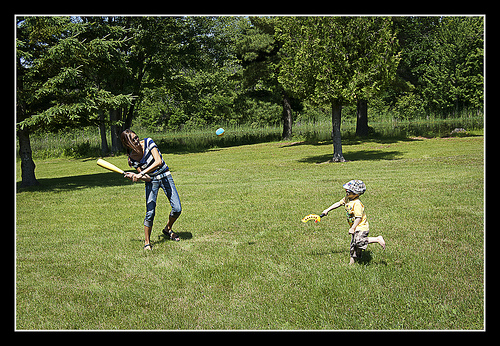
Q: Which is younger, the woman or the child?
A: The child is younger than the woman.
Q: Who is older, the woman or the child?
A: The woman is older than the child.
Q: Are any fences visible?
A: No, there are no fences.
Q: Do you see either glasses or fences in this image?
A: No, there are no fences or glasses.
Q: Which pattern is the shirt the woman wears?
A: The shirt is striped.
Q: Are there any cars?
A: No, there are no cars.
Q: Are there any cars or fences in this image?
A: No, there are no cars or fences.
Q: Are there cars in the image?
A: No, there are no cars.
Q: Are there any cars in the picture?
A: No, there are no cars.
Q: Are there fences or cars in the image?
A: No, there are no cars or fences.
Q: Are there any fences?
A: No, there are no fences.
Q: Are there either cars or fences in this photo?
A: No, there are no fences or cars.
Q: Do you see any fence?
A: No, there are no fences.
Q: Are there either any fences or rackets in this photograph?
A: No, there are no fences or rackets.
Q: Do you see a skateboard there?
A: No, there are no skateboards.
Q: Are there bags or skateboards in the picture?
A: No, there are no skateboards or bags.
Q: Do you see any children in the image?
A: Yes, there is a child.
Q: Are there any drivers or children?
A: Yes, there is a child.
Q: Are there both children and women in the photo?
A: Yes, there are both a child and a woman.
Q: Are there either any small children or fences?
A: Yes, there is a small child.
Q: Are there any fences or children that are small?
A: Yes, the child is small.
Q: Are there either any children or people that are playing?
A: Yes, the child is playing.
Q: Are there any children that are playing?
A: Yes, there is a child that is playing.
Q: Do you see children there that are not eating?
A: Yes, there is a child that is playing .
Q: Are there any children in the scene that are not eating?
A: Yes, there is a child that is playing.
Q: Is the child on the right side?
A: Yes, the child is on the right of the image.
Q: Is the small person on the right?
A: Yes, the child is on the right of the image.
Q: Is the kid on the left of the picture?
A: No, the kid is on the right of the image.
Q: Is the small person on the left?
A: No, the kid is on the right of the image.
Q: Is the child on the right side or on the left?
A: The child is on the right of the image.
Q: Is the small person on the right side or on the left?
A: The child is on the right of the image.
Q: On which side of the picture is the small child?
A: The child is on the right of the image.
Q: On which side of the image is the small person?
A: The child is on the right of the image.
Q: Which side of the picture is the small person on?
A: The child is on the right of the image.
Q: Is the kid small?
A: Yes, the kid is small.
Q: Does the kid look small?
A: Yes, the kid is small.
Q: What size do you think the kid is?
A: The kid is small.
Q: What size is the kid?
A: The kid is small.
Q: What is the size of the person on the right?
A: The kid is small.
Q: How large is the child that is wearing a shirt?
A: The child is small.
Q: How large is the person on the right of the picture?
A: The child is small.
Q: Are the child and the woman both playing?
A: Yes, both the child and the woman are playing.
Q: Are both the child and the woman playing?
A: Yes, both the child and the woman are playing.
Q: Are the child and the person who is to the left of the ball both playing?
A: Yes, both the child and the woman are playing.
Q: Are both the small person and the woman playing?
A: Yes, both the child and the woman are playing.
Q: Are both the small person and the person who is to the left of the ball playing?
A: Yes, both the child and the woman are playing.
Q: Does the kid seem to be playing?
A: Yes, the kid is playing.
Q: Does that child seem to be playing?
A: Yes, the child is playing.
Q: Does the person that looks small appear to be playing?
A: Yes, the child is playing.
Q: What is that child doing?
A: The child is playing.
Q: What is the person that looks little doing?
A: The child is playing.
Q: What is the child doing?
A: The child is playing.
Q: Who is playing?
A: The kid is playing.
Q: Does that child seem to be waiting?
A: No, the child is playing.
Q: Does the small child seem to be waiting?
A: No, the kid is playing.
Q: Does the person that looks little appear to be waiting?
A: No, the kid is playing.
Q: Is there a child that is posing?
A: No, there is a child but he is playing.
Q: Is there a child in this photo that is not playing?
A: No, there is a child but he is playing.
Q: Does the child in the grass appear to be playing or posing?
A: The child is playing.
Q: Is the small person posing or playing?
A: The child is playing.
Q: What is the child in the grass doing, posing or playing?
A: The kid is playing.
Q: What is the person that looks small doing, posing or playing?
A: The kid is playing.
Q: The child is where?
A: The child is in the grass.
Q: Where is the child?
A: The child is in the grass.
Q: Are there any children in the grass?
A: Yes, there is a child in the grass.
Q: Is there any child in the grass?
A: Yes, there is a child in the grass.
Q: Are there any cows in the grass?
A: No, there is a child in the grass.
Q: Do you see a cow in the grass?
A: No, there is a child in the grass.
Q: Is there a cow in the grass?
A: No, there is a child in the grass.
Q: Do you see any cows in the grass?
A: No, there is a child in the grass.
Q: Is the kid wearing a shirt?
A: Yes, the kid is wearing a shirt.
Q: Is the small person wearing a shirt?
A: Yes, the kid is wearing a shirt.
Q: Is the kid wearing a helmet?
A: No, the kid is wearing a shirt.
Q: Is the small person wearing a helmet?
A: No, the kid is wearing a shirt.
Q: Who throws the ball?
A: The kid throws the ball.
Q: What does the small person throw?
A: The child throws the ball.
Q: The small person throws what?
A: The child throws the ball.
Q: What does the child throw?
A: The child throws the ball.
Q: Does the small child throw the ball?
A: Yes, the kid throws the ball.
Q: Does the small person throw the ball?
A: Yes, the kid throws the ball.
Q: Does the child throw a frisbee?
A: No, the child throws the ball.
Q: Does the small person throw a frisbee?
A: No, the child throws the ball.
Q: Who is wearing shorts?
A: The kid is wearing shorts.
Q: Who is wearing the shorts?
A: The kid is wearing shorts.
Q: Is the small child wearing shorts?
A: Yes, the kid is wearing shorts.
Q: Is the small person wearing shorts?
A: Yes, the kid is wearing shorts.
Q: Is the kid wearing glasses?
A: No, the kid is wearing shorts.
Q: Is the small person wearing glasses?
A: No, the kid is wearing shorts.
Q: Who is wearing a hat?
A: The kid is wearing a hat.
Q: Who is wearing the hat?
A: The kid is wearing a hat.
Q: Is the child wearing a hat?
A: Yes, the child is wearing a hat.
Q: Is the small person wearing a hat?
A: Yes, the child is wearing a hat.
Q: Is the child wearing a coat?
A: No, the child is wearing a hat.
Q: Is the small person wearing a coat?
A: No, the child is wearing a hat.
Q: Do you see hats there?
A: Yes, there is a hat.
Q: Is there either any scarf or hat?
A: Yes, there is a hat.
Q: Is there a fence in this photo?
A: No, there are no fences.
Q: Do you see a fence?
A: No, there are no fences.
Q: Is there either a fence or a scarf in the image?
A: No, there are no fences or scarves.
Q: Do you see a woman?
A: Yes, there is a woman.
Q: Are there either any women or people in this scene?
A: Yes, there is a woman.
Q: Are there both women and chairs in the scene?
A: No, there is a woman but no chairs.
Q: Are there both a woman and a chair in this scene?
A: No, there is a woman but no chairs.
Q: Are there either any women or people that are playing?
A: Yes, the woman is playing.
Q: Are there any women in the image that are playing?
A: Yes, there is a woman that is playing.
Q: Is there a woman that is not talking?
A: Yes, there is a woman that is playing.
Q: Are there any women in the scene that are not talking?
A: Yes, there is a woman that is playing.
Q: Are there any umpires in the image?
A: No, there are no umpires.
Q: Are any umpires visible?
A: No, there are no umpires.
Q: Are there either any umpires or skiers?
A: No, there are no umpires or skiers.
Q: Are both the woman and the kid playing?
A: Yes, both the woman and the kid are playing.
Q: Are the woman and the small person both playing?
A: Yes, both the woman and the kid are playing.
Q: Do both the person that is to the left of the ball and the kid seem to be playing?
A: Yes, both the woman and the kid are playing.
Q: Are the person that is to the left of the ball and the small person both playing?
A: Yes, both the woman and the kid are playing.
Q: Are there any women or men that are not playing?
A: No, there is a woman but she is playing.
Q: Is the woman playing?
A: Yes, the woman is playing.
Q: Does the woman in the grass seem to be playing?
A: Yes, the woman is playing.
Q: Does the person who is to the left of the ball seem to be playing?
A: Yes, the woman is playing.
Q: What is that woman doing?
A: The woman is playing.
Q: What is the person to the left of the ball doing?
A: The woman is playing.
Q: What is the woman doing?
A: The woman is playing.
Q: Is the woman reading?
A: No, the woman is playing.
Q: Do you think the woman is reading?
A: No, the woman is playing.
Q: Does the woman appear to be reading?
A: No, the woman is playing.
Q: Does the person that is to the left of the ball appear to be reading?
A: No, the woman is playing.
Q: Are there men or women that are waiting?
A: No, there is a woman but she is playing.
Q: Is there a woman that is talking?
A: No, there is a woman but she is playing.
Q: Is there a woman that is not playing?
A: No, there is a woman but she is playing.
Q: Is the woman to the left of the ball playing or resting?
A: The woman is playing.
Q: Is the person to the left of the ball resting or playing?
A: The woman is playing.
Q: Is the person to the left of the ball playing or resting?
A: The woman is playing.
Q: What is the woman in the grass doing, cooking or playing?
A: The woman is playing.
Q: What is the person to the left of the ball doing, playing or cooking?
A: The woman is playing.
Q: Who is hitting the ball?
A: The woman is hitting the ball.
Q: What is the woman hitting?
A: The woman is hitting the ball.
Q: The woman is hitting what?
A: The woman is hitting the ball.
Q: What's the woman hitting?
A: The woman is hitting the ball.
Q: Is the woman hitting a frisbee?
A: No, the woman is hitting the ball.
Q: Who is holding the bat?
A: The woman is holding the bat.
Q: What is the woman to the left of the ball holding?
A: The woman is holding the bat.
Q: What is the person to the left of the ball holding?
A: The woman is holding the bat.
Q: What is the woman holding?
A: The woman is holding the bat.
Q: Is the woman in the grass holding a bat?
A: Yes, the woman is holding a bat.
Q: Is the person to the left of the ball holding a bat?
A: Yes, the woman is holding a bat.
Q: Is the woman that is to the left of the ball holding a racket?
A: No, the woman is holding a bat.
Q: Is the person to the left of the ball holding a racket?
A: No, the woman is holding a bat.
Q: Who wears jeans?
A: The woman wears jeans.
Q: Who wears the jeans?
A: The woman wears jeans.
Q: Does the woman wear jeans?
A: Yes, the woman wears jeans.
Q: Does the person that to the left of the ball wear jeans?
A: Yes, the woman wears jeans.